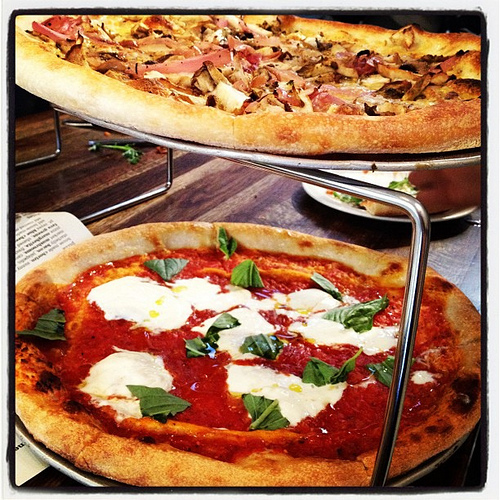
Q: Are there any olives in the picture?
A: No, there are no olives.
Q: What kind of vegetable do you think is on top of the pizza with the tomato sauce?
A: The vegetable is basil.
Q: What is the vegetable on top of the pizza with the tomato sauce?
A: The vegetable is basil.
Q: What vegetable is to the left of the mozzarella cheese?
A: The vegetable is basil.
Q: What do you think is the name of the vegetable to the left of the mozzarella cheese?
A: The vegetable is basil.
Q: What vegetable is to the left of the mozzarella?
A: The vegetable is basil.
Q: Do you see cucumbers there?
A: No, there are no cucumbers.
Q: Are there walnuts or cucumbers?
A: No, there are no cucumbers or walnuts.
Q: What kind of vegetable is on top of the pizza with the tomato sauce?
A: The vegetable is basil.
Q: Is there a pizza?
A: Yes, there is a pizza.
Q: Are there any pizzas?
A: Yes, there is a pizza.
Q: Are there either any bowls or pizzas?
A: Yes, there is a pizza.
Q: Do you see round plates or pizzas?
A: Yes, there is a round pizza.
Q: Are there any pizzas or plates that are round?
A: Yes, the pizza is round.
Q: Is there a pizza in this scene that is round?
A: Yes, there is a round pizza.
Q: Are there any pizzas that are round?
A: Yes, there is a pizza that is round.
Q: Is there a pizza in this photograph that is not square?
A: Yes, there is a round pizza.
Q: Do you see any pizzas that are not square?
A: Yes, there is a round pizza.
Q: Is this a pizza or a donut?
A: This is a pizza.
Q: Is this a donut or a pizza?
A: This is a pizza.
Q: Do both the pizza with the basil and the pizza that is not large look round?
A: Yes, both the pizza and the pizza are round.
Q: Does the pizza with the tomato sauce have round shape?
A: Yes, the pizza is round.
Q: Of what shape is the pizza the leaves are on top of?
A: The pizza is round.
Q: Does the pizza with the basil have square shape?
A: No, the pizza is round.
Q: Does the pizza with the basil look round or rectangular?
A: The pizza is round.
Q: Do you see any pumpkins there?
A: No, there are no pumpkins.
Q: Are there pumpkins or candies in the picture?
A: No, there are no pumpkins or candies.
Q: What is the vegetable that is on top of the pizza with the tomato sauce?
A: The vegetable is basil.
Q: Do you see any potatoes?
A: No, there are no potatoes.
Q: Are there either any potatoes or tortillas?
A: No, there are no potatoes or tortillas.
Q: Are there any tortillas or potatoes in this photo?
A: No, there are no potatoes or tortillas.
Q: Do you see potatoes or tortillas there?
A: No, there are no potatoes or tortillas.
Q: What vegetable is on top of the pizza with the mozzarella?
A: The vegetable is basil.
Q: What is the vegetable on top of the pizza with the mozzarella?
A: The vegetable is basil.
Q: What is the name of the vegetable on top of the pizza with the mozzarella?
A: The vegetable is basil.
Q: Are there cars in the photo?
A: No, there are no cars.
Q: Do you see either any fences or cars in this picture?
A: No, there are no cars or fences.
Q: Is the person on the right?
A: Yes, the person is on the right of the image.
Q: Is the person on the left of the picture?
A: No, the person is on the right of the image.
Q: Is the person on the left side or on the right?
A: The person is on the right of the image.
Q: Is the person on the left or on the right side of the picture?
A: The person is on the right of the image.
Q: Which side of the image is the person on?
A: The person is on the right of the image.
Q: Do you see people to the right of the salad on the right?
A: Yes, there is a person to the right of the salad.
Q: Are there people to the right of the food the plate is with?
A: Yes, there is a person to the right of the salad.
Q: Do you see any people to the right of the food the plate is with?
A: Yes, there is a person to the right of the salad.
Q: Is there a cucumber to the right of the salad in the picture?
A: No, there is a person to the right of the salad.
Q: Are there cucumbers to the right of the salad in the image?
A: No, there is a person to the right of the salad.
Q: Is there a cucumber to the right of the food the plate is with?
A: No, there is a person to the right of the salad.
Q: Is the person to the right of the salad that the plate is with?
A: Yes, the person is to the right of the salad.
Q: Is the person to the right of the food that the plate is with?
A: Yes, the person is to the right of the salad.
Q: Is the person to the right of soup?
A: No, the person is to the right of the salad.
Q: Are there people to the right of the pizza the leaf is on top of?
A: Yes, there is a person to the right of the pizza.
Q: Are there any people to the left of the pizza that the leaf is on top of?
A: No, the person is to the right of the pizza.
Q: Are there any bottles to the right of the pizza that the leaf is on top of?
A: No, there is a person to the right of the pizza.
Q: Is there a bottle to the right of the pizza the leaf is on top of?
A: No, there is a person to the right of the pizza.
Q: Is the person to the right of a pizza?
A: Yes, the person is to the right of a pizza.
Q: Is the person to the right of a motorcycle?
A: No, the person is to the right of a pizza.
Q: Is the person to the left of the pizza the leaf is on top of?
A: No, the person is to the right of the pizza.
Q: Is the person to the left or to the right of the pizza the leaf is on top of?
A: The person is to the right of the pizza.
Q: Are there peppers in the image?
A: No, there are no peppers.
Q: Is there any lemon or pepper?
A: No, there are no peppers or lemons.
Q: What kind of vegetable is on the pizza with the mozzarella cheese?
A: The vegetable is basil.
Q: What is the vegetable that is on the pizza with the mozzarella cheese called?
A: The vegetable is basil.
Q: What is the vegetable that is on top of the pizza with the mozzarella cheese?
A: The vegetable is basil.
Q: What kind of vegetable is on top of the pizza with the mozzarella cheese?
A: The vegetable is basil.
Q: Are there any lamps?
A: No, there are no lamps.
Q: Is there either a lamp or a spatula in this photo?
A: No, there are no lamps or spatulas.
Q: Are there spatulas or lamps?
A: No, there are no lamps or spatulas.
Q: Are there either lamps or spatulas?
A: No, there are no lamps or spatulas.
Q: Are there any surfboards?
A: No, there are no surfboards.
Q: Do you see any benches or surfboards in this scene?
A: No, there are no surfboards or benches.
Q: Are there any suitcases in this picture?
A: No, there are no suitcases.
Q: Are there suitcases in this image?
A: No, there are no suitcases.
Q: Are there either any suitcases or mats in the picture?
A: No, there are no suitcases or mats.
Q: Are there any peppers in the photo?
A: No, there are no peppers.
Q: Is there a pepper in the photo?
A: No, there are no peppers.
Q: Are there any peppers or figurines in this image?
A: No, there are no peppers or figurines.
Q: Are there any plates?
A: Yes, there is a plate.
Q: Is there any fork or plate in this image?
A: Yes, there is a plate.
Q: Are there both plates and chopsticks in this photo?
A: No, there is a plate but no chopsticks.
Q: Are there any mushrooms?
A: Yes, there are mushrooms.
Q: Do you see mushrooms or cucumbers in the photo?
A: Yes, there are mushrooms.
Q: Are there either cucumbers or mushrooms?
A: Yes, there are mushrooms.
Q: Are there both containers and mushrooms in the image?
A: No, there are mushrooms but no containers.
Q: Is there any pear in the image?
A: No, there are no pears.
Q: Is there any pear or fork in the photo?
A: No, there are no pears or forks.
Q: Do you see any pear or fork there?
A: No, there are no pears or forks.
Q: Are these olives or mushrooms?
A: These are mushrooms.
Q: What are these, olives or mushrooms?
A: These are mushrooms.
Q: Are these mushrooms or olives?
A: These are mushrooms.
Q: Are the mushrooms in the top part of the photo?
A: Yes, the mushrooms are in the top of the image.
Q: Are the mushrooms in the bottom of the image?
A: No, the mushrooms are in the top of the image.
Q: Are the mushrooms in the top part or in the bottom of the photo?
A: The mushrooms are in the top of the image.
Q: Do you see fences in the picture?
A: No, there are no fences.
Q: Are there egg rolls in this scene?
A: No, there are no egg rolls.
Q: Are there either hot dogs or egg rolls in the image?
A: No, there are no egg rolls or hot dogs.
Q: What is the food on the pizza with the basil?
A: The food is mozzarella.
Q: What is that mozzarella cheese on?
A: The mozzarella cheese is on the pizza.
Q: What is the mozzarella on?
A: The mozzarella cheese is on the pizza.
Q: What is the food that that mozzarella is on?
A: The food is a pizza.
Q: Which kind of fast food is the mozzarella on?
A: The mozzarella is on the pizza.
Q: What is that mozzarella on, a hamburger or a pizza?
A: The mozzarella is on a pizza.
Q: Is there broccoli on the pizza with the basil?
A: No, there is mozzarella on the pizza.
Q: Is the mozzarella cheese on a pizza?
A: Yes, the mozzarella cheese is on a pizza.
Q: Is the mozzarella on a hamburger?
A: No, the mozzarella is on a pizza.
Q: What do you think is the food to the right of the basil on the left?
A: The food is mozzarella.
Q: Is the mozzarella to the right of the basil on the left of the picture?
A: Yes, the mozzarella is to the right of the basil.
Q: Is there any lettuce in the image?
A: No, there is no lettuce.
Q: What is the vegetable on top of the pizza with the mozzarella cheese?
A: The vegetable is basil.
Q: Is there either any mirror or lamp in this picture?
A: No, there are no lamps or mirrors.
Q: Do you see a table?
A: Yes, there is a table.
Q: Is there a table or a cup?
A: Yes, there is a table.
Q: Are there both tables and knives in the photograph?
A: No, there is a table but no knives.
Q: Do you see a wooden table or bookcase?
A: Yes, there is a wood table.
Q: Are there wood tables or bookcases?
A: Yes, there is a wood table.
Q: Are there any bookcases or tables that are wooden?
A: Yes, the table is wooden.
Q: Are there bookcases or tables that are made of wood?
A: Yes, the table is made of wood.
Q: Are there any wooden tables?
A: Yes, there is a wood table.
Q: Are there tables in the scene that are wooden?
A: Yes, there is a table that is wooden.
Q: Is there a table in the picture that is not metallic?
A: Yes, there is a wooden table.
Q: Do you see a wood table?
A: Yes, there is a table that is made of wood.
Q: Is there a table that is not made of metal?
A: Yes, there is a table that is made of wood.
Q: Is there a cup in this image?
A: No, there are no cups.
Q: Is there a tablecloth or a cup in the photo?
A: No, there are no cups or tablecloths.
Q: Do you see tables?
A: Yes, there is a table.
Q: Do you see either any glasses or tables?
A: Yes, there is a table.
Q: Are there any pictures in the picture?
A: No, there are no pictures.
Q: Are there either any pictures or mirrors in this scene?
A: No, there are no pictures or mirrors.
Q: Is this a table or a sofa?
A: This is a table.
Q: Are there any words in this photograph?
A: Yes, there are words.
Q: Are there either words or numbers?
A: Yes, there are words.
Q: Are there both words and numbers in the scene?
A: No, there are words but no numbers.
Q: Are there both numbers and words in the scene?
A: No, there are words but no numbers.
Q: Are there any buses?
A: No, there are no buses.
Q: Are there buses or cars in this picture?
A: No, there are no buses or cars.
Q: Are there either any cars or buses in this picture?
A: No, there are no buses or cars.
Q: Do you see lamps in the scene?
A: No, there are no lamps.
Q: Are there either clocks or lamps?
A: No, there are no lamps or clocks.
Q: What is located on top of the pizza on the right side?
A: The leaf is on top of the pizza.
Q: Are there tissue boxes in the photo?
A: No, there are no tissue boxes.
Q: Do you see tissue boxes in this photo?
A: No, there are no tissue boxes.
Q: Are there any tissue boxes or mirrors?
A: No, there are no tissue boxes or mirrors.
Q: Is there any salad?
A: Yes, there is salad.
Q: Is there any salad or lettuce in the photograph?
A: Yes, there is salad.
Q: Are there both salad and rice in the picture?
A: No, there is salad but no rice.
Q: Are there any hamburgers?
A: No, there are no hamburgers.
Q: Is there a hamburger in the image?
A: No, there are no hamburgers.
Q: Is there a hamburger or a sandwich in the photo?
A: No, there are no hamburgers or sandwiches.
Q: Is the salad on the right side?
A: Yes, the salad is on the right of the image.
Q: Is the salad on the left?
A: No, the salad is on the right of the image.